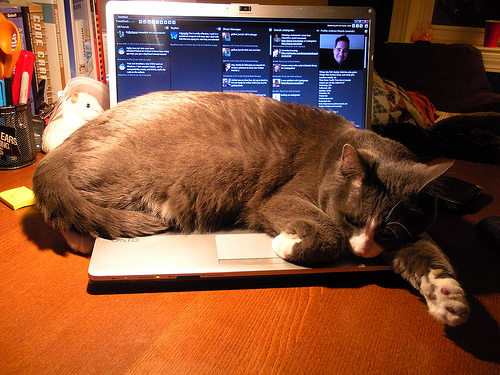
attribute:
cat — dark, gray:
[33, 89, 468, 327]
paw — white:
[390, 232, 469, 326]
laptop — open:
[88, 0, 395, 284]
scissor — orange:
[0, 14, 23, 107]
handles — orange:
[0, 12, 23, 78]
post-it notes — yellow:
[0, 186, 36, 211]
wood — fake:
[4, 151, 498, 373]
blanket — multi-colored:
[371, 68, 441, 130]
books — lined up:
[0, 0, 108, 103]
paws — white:
[270, 219, 471, 328]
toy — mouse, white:
[41, 92, 103, 154]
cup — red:
[483, 19, 500, 50]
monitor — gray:
[106, 1, 377, 128]